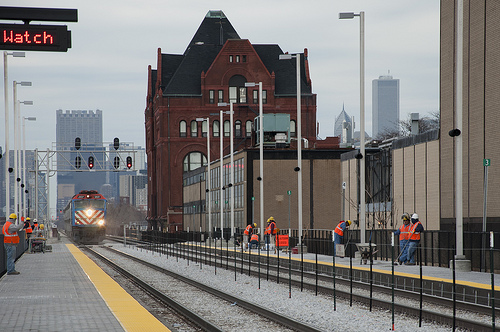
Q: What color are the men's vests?
A: Orange.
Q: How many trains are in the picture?
A: One.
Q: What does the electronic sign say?
A: Watch.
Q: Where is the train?
A: On the tracks.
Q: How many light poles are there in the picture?
A: Eleven.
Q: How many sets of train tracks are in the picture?
A: Two.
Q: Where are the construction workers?
A: On the platform.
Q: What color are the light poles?
A: White.